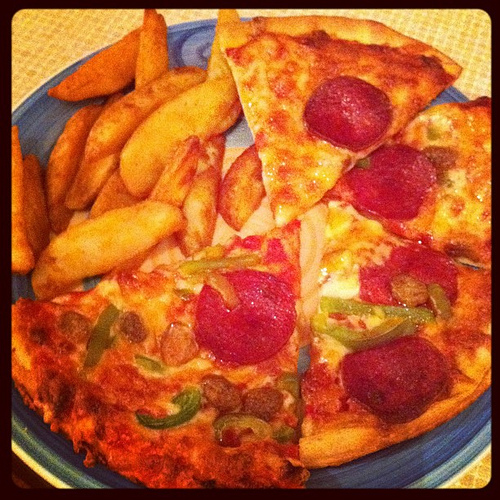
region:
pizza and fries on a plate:
[46, 80, 454, 445]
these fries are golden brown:
[36, 48, 228, 228]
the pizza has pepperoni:
[33, 244, 319, 466]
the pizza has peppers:
[53, 309, 222, 443]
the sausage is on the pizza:
[206, 368, 286, 428]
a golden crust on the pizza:
[214, 7, 470, 69]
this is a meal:
[74, 148, 431, 408]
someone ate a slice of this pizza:
[59, 47, 406, 422]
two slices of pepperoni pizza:
[265, 42, 470, 227]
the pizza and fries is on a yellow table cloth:
[19, 17, 488, 102]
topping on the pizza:
[204, 379, 244, 414]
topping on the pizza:
[352, 326, 407, 358]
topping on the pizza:
[355, 358, 440, 409]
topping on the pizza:
[203, 391, 235, 424]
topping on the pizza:
[195, 290, 265, 362]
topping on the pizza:
[363, 168, 438, 225]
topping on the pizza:
[307, 81, 387, 138]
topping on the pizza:
[99, 339, 146, 378]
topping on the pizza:
[123, 317, 144, 347]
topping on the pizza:
[201, 420, 265, 447]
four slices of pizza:
[2, 14, 494, 494]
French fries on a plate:
[17, 14, 262, 288]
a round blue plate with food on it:
[12, 18, 490, 491]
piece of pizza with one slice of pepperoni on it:
[225, 18, 463, 228]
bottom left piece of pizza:
[1, 220, 299, 495]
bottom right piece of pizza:
[306, 210, 496, 467]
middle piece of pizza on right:
[329, 93, 492, 268]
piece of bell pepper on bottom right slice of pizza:
[316, 300, 434, 347]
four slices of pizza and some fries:
[17, 28, 490, 485]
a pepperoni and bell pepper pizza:
[15, 25, 490, 480]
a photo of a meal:
[36, 61, 434, 422]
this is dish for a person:
[67, 84, 420, 379]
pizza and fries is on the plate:
[62, 119, 439, 419]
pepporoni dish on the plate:
[65, 98, 450, 338]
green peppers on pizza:
[91, 264, 440, 435]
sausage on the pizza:
[186, 361, 291, 425]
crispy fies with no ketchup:
[28, 68, 238, 234]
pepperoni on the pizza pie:
[208, 85, 453, 398]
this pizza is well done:
[233, 11, 458, 236]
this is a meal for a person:
[67, 72, 432, 414]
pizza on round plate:
[197, 37, 494, 485]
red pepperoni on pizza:
[336, 61, 436, 255]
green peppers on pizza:
[326, 257, 493, 366]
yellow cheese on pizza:
[330, 211, 375, 280]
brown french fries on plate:
[11, 41, 297, 278]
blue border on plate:
[63, 48, 488, 498]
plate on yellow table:
[6, 11, 484, 489]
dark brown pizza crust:
[47, 313, 214, 475]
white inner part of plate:
[199, 126, 286, 265]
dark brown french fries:
[27, 71, 254, 247]